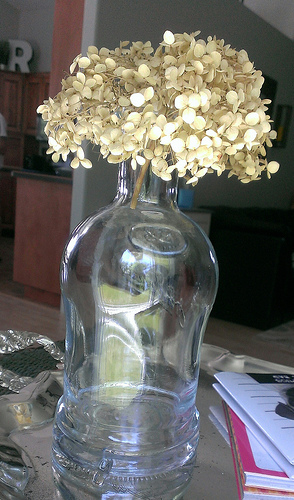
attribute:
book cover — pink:
[226, 416, 242, 445]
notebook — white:
[211, 370, 293, 479]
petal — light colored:
[161, 29, 175, 46]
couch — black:
[198, 204, 293, 332]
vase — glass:
[56, 160, 228, 488]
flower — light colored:
[55, 52, 249, 182]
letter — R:
[10, 35, 36, 76]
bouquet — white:
[41, 29, 232, 161]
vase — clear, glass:
[28, 176, 232, 423]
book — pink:
[214, 380, 289, 498]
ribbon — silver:
[0, 305, 47, 386]